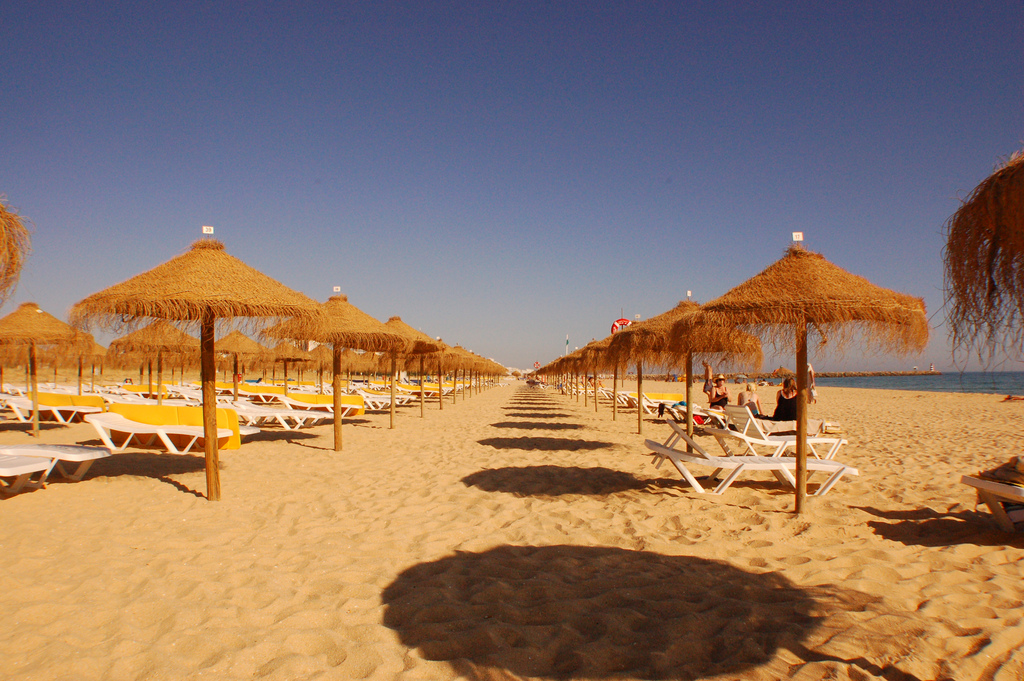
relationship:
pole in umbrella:
[197, 306, 224, 500] [73, 232, 321, 502]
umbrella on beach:
[359, 314, 432, 422] [12, 383, 1012, 677]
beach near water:
[0, 369, 1022, 679] [656, 369, 1021, 401]